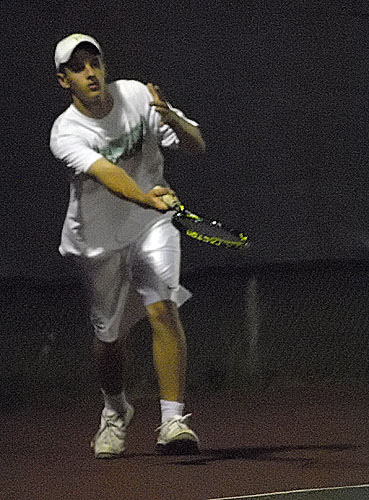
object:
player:
[47, 32, 207, 460]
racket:
[154, 173, 251, 253]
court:
[0, 258, 368, 498]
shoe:
[90, 402, 135, 456]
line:
[212, 466, 368, 496]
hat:
[54, 32, 104, 72]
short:
[74, 216, 193, 348]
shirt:
[50, 78, 199, 261]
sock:
[158, 395, 186, 430]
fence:
[269, 249, 320, 336]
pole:
[231, 269, 270, 387]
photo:
[0, 2, 368, 497]